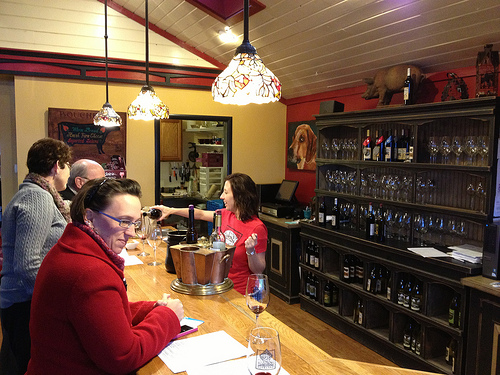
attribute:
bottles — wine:
[163, 183, 265, 296]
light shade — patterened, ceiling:
[92, 99, 124, 129]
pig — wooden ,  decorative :
[356, 62, 431, 105]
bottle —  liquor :
[398, 62, 416, 104]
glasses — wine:
[323, 169, 434, 199]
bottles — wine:
[360, 125, 413, 162]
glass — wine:
[422, 213, 474, 258]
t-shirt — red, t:
[216, 213, 266, 296]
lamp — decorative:
[83, 4, 124, 147]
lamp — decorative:
[130, 10, 170, 127]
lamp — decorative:
[207, 8, 287, 115]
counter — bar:
[102, 247, 328, 374]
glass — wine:
[415, 133, 440, 164]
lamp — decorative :
[213, 24, 299, 121]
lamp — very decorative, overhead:
[214, 3, 280, 107]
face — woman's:
[92, 192, 140, 255]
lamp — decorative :
[129, 90, 169, 121]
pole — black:
[240, 3, 252, 52]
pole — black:
[141, 1, 155, 90]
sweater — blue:
[3, 179, 66, 297]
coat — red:
[15, 224, 178, 371]